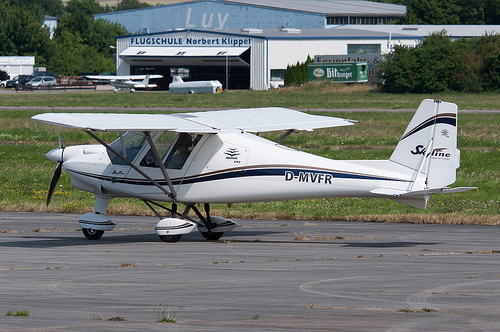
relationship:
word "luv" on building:
[179, 3, 231, 31] [91, 2, 412, 89]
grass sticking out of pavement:
[99, 309, 188, 326] [5, 209, 494, 331]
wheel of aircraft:
[158, 233, 182, 245] [27, 97, 478, 241]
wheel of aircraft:
[199, 228, 225, 244] [27, 97, 478, 241]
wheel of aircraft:
[80, 227, 103, 244] [27, 97, 478, 241]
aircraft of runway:
[27, 97, 478, 241] [1, 211, 498, 328]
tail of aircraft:
[374, 99, 457, 209] [27, 97, 478, 241]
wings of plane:
[25, 70, 362, 165] [28, 47, 476, 252]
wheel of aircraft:
[80, 227, 103, 244] [31, 99, 478, 242]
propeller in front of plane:
[39, 125, 67, 205] [17, 78, 484, 244]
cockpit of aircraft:
[110, 128, 205, 177] [19, 80, 486, 245]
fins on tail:
[396, 89, 479, 201] [374, 99, 457, 209]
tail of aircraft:
[374, 99, 457, 209] [19, 80, 486, 245]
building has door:
[113, 32, 417, 89] [119, 46, 249, 86]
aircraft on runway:
[27, 97, 478, 241] [1, 211, 498, 328]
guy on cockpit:
[169, 133, 194, 168] [106, 128, 203, 172]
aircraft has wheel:
[27, 97, 478, 241] [197, 211, 244, 248]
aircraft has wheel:
[27, 97, 478, 241] [154, 216, 190, 243]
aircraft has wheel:
[27, 97, 478, 241] [75, 211, 109, 241]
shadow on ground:
[0, 230, 447, 250] [39, 194, 498, 316]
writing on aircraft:
[282, 170, 334, 186] [27, 97, 478, 241]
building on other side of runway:
[241, 22, 417, 90] [1, 211, 498, 328]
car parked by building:
[25, 74, 57, 91] [111, 25, 498, 90]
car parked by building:
[1, 74, 33, 91] [111, 25, 498, 90]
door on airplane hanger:
[119, 46, 249, 86] [112, 22, 428, 91]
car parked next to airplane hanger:
[25, 74, 57, 91] [112, 28, 426, 91]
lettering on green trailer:
[322, 66, 354, 78] [307, 62, 367, 85]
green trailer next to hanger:
[307, 62, 367, 85] [110, 21, 425, 109]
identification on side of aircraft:
[276, 163, 336, 184] [27, 97, 478, 241]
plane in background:
[87, 72, 163, 94] [1, 14, 498, 114]